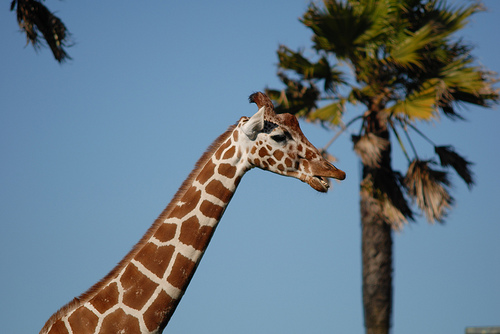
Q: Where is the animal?
A: Near a tree.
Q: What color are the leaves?
A: Green.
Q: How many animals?
A: One.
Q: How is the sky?
A: Clear.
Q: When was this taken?
A: During the day.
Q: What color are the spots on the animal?
A: Brown.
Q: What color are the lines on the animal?
A: Cream.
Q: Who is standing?
A: Giraffe.